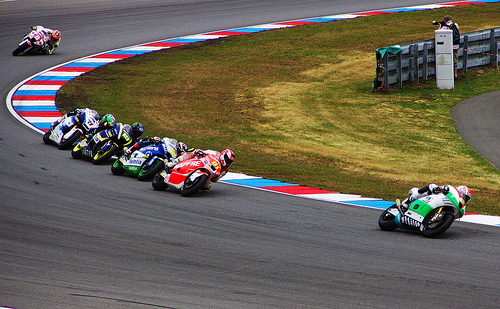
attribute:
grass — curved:
[255, 42, 498, 180]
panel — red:
[12, 71, 68, 91]